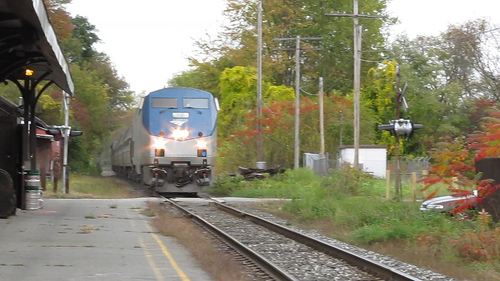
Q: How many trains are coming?
A: One.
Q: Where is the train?
A: On the track.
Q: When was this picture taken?
A: During the daytime.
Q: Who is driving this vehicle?
A: The engineer.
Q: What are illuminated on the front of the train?
A: Headlights.